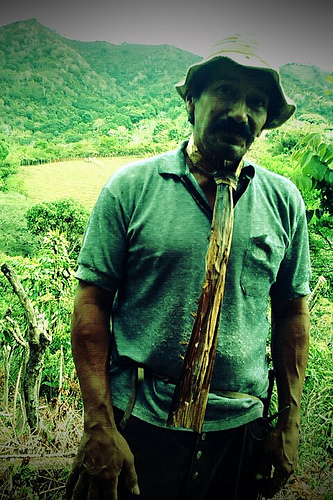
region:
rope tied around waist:
[109, 348, 265, 435]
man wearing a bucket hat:
[172, 33, 296, 130]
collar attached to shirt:
[157, 140, 255, 180]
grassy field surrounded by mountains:
[17, 154, 145, 213]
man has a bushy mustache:
[207, 116, 253, 147]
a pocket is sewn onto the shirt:
[239, 235, 284, 298]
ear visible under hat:
[183, 86, 193, 115]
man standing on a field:
[28, 24, 320, 498]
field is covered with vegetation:
[3, 2, 330, 498]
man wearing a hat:
[44, 14, 319, 498]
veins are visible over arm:
[247, 304, 319, 495]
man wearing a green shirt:
[42, 22, 323, 498]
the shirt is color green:
[67, 138, 317, 439]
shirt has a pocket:
[66, 141, 321, 439]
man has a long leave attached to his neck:
[58, 26, 317, 445]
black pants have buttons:
[190, 419, 210, 489]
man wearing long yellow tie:
[168, 179, 246, 432]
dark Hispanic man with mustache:
[61, 35, 315, 495]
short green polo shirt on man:
[72, 131, 320, 428]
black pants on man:
[63, 418, 274, 496]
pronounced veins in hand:
[76, 400, 123, 483]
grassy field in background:
[5, 154, 135, 222]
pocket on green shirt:
[241, 229, 294, 301]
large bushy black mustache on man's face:
[199, 118, 256, 140]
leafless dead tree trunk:
[5, 258, 61, 450]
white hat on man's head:
[173, 32, 295, 127]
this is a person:
[48, 38, 318, 494]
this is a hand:
[57, 209, 145, 497]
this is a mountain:
[70, 24, 197, 122]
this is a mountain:
[0, 13, 124, 139]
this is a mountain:
[286, 51, 329, 132]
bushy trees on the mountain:
[40, 87, 93, 140]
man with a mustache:
[61, 28, 312, 498]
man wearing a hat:
[57, 28, 322, 495]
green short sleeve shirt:
[70, 144, 305, 434]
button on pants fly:
[195, 448, 203, 458]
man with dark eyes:
[58, 30, 312, 497]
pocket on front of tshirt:
[237, 233, 287, 300]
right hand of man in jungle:
[61, 431, 139, 499]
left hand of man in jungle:
[258, 426, 298, 498]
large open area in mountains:
[12, 146, 187, 215]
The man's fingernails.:
[134, 480, 145, 493]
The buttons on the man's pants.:
[191, 429, 214, 473]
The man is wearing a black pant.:
[112, 417, 256, 494]